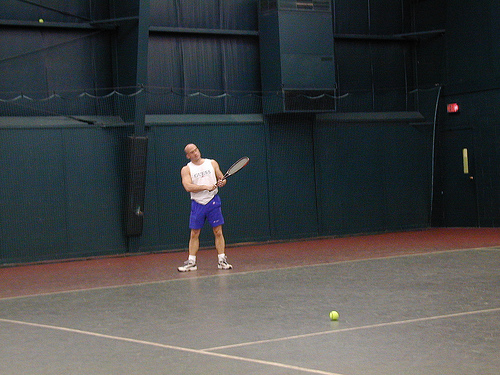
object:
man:
[178, 143, 233, 273]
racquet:
[209, 156, 249, 192]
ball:
[330, 310, 338, 319]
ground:
[1, 228, 500, 375]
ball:
[39, 19, 43, 23]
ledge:
[0, 20, 118, 30]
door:
[441, 128, 479, 226]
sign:
[445, 102, 460, 118]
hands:
[207, 184, 216, 192]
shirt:
[186, 159, 219, 205]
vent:
[257, 2, 335, 114]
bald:
[185, 144, 197, 153]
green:
[257, 0, 335, 116]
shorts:
[189, 194, 224, 229]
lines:
[0, 315, 333, 374]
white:
[189, 255, 197, 259]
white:
[218, 253, 224, 257]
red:
[243, 162, 248, 166]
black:
[224, 173, 230, 178]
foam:
[0, 119, 432, 268]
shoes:
[177, 260, 197, 272]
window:
[463, 148, 469, 173]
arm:
[180, 166, 206, 192]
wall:
[319, 128, 430, 234]